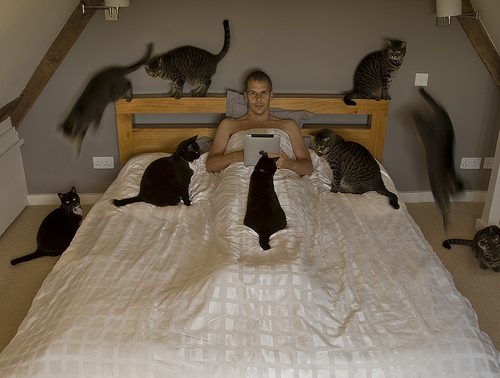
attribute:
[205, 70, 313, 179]
man — bare chested, light skinned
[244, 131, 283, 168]
ipad — white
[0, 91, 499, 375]
bed — wooden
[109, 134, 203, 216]
cat — black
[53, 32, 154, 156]
cat — jumping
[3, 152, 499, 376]
sheet — white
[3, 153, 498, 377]
bedspread — white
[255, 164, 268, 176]
collar — red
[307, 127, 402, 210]
cat — striped, gray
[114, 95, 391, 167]
headboard — pine, wooden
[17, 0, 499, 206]
wall — gray, beige, white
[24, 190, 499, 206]
baseboard — white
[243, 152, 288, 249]
fur — black